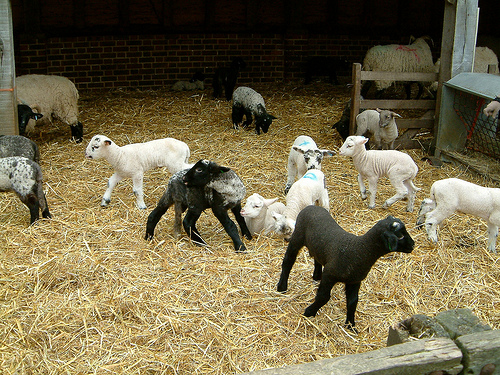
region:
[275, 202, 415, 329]
Black lamb standing in hay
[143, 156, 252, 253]
Black and white lamb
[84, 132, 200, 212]
Small white lamb walking in hay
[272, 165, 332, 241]
White lamb with a blue marking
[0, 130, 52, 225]
Back of two gray and white lambs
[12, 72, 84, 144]
Tan sheep with a black face and legs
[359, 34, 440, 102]
Sheep with a red marking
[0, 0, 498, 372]
Fenced in sheep and lamb home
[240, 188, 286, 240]
Lamb laying in the hay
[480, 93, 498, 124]
A person's hand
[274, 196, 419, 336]
black sheep looking right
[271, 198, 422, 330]
black sheep in pen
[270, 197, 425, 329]
black sheep standing in pen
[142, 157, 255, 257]
black and white sheep looking left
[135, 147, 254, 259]
black and white sheep in pen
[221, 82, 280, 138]
small black and white sheep near fence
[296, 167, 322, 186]
blue marking on sheep's back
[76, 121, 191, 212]
white sheep facing left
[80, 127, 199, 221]
white sheep standing in pen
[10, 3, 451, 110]
brick wall enclosure behind sheep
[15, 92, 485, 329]
a group of animals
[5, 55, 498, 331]
a group of sheeps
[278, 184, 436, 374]
a black sheep in grass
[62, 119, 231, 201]
a white sheep in grass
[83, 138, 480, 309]
a group of white and black animals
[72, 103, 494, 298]
a group of white and black sheeps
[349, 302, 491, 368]
a wood near the sheep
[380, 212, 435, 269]
face of the sheep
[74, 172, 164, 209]
leg of the sheep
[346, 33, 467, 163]
a table in the back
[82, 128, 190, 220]
white baby lamp behind black baby lamb grooming himself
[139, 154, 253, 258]
mostly back baby lamb grooming himself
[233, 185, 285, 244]
white baby lamb lying in the hay next to lamb grooming himself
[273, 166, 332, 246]
white baby lamb eating hay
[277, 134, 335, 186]
white baby lamb behind white baby lamb eating hay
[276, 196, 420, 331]
black baby lamb in front of white baby lamb eating hay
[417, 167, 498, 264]
white baby lamb at right middle of photo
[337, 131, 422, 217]
white baby lamb taking a step in the hay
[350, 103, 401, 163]
grayish colored baby lamb against a wooden pallet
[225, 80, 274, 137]
grey lamb with black head and legs eating hay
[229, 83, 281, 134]
sheep is not full grown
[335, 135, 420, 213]
sheep is white in color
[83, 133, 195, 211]
sheep has black spot on head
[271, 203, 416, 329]
sheep has black wool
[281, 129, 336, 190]
sheep has blue on it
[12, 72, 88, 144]
sheep has lots of wool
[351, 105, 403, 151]
sheep is in front of fence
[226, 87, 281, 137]
sheep is eating straw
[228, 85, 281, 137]
sheep is standing up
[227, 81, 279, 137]
sheep is on straw